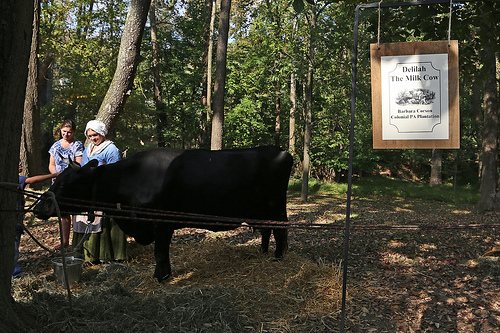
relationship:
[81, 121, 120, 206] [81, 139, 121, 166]
person wearing shirt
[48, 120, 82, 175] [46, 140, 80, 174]
person wearing shirt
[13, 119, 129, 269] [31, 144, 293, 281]
people standing next cow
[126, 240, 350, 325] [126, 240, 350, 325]
hay standing in hay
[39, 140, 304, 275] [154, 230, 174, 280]
cow has leg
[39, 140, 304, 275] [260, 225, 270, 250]
cow has leg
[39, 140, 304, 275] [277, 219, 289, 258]
cow has leg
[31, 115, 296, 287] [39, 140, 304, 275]
two people looking at cow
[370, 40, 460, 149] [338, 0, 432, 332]
sign hanging from bar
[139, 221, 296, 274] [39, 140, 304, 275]
four legs of cow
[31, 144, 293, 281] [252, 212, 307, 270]
cow has legs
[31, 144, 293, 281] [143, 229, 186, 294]
cow has legs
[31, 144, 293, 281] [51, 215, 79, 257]
cow has legs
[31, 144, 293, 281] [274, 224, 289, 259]
cow has leg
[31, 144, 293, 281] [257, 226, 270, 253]
cow has leg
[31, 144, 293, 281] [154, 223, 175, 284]
cow has leg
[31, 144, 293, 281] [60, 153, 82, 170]
cow has ear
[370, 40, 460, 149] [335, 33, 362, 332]
sign on pole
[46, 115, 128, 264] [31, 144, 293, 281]
two people by cow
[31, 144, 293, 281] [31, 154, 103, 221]
cow has head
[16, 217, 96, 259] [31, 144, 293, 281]
rope on cow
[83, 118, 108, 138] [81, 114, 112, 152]
bonnet on head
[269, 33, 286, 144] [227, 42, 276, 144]
tree has leaves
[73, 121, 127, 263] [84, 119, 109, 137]
woman has bonnet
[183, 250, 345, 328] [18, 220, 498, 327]
hay on ground